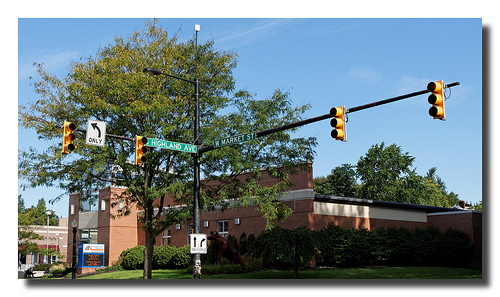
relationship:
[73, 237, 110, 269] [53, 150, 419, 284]
sign outside of building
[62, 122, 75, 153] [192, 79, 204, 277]
stop light on a pole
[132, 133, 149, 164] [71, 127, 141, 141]
stop light on a pole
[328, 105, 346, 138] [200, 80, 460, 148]
traffic signal on pole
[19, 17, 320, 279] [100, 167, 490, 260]
trees are in front of building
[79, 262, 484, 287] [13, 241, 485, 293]
green grass on ground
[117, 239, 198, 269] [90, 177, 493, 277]
bushes are near building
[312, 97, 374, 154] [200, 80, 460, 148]
light on pole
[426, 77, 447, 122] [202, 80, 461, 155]
light on pole